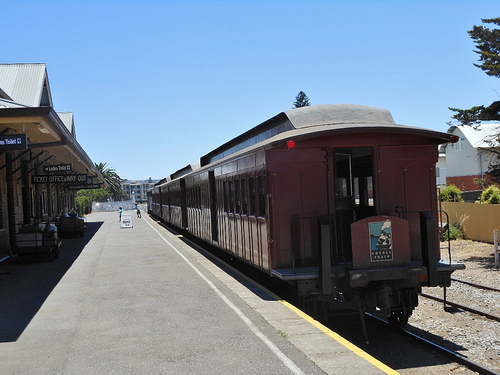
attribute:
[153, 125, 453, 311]
train — at station, stationary, red, parked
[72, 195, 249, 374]
sidewalk — concrete, grey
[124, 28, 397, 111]
sky — blue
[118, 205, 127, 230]
sign — black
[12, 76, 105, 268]
building — white, light-colored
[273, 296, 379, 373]
line — yellow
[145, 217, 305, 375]
line — white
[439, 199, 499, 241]
fence — brown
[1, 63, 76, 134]
roofs — pointed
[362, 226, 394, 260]
logo — blue